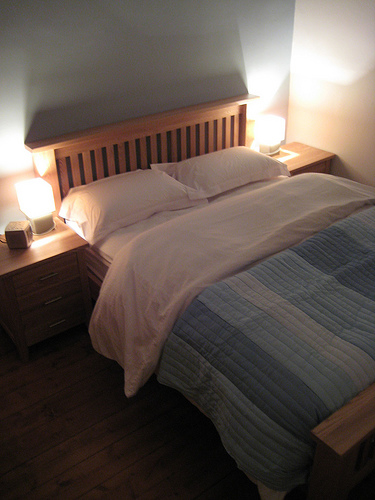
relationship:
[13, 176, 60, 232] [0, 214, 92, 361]
light on nightstand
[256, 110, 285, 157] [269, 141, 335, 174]
light on nightstand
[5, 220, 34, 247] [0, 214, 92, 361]
clock on nightstand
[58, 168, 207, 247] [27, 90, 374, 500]
pillow on bed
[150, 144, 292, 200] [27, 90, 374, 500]
pillow on bed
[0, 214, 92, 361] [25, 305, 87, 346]
nightstand has drawer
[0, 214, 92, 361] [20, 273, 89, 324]
nightstand has drawer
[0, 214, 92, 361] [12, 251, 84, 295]
nightstand has drawer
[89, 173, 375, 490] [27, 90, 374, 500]
comforter on bed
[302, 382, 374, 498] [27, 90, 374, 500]
footboard on bed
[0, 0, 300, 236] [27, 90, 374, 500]
wall behind bed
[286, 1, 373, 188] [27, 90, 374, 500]
wall right of bed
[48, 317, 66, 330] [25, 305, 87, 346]
handle on drawer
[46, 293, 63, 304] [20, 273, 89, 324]
handle on drawer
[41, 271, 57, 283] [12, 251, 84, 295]
handle on drawer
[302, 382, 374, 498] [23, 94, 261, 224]
footboard matches headboard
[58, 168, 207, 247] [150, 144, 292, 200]
pillow near pillow